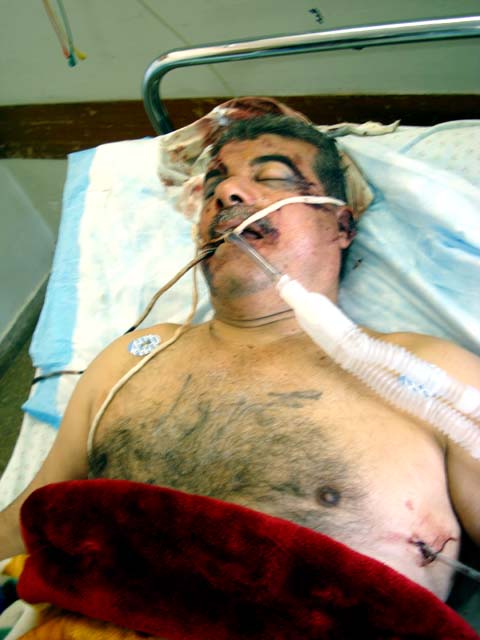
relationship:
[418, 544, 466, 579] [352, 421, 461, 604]
needle stuck into side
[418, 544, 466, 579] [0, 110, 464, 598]
needle stuck into man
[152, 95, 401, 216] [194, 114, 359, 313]
cloth lying on top of head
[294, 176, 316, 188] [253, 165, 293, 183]
cut injuring eye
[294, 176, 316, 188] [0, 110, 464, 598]
cut injuring man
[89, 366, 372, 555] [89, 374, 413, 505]
hair on chest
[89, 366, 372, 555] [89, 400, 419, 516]
hair on chest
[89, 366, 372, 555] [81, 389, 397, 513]
hair on chest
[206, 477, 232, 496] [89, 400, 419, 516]
hair on chest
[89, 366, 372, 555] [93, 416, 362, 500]
hair on chest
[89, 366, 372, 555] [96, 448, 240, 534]
hair on chest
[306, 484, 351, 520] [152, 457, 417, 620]
nipple on chest